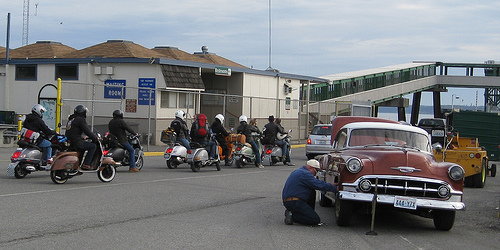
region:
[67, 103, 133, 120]
the helmets are black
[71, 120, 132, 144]
the clothing is black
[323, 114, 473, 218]
the car is brown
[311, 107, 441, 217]
the car is under repair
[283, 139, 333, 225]
the man is kneeling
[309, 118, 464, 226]
the car is a classic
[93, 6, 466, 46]
the sky is cloudy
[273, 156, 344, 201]
the man has a blue shirt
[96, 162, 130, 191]
the tyre has a white stripe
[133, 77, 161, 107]
there is blue writing on the wall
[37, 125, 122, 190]
A brown motor bike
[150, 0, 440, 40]
A mostly cloudy sky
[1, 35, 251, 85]
Brown, triangular roof tops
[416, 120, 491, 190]
A yellow car trailer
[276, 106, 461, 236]
A man fixing his car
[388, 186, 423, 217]
The car's license plate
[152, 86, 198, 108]
Windows on the building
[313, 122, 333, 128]
A car's brake light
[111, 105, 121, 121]
A black helmet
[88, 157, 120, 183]
A motor bike wheel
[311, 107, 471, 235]
A red classic car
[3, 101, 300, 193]
A group riding their motor bikes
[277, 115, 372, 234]
A man changing his tire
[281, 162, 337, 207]
A blue long sleeve shirt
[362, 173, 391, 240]
A metal car jack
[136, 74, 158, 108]
A blue sign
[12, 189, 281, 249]
A crack in the street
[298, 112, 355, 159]
The back of a silver car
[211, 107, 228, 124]
A white helmet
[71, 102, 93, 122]
A black helmet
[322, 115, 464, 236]
An older car is on the side on the road.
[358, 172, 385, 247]
There is a jack on the front bumper.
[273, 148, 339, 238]
The man is kneeling on the ground.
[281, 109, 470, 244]
The man is changing a tire.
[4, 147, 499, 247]
The asphalt is dry.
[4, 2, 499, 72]
The sky is blue with white ripples of clouds.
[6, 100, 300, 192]
Many people are riding motorcycles down the street.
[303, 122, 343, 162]
There is a white car in front of all the motorcycles.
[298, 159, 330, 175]
The man is wearing a white cap.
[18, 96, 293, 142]
Most of the motorcyclists are wearing helmets.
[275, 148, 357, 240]
the man is fixing his tire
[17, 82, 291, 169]
the people are riding the motorcycles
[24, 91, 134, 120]
people are wearing helmets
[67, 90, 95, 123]
the helmet is black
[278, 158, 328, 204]
the shirt is blue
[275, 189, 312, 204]
the belt is brown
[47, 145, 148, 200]
the motorcycle is brown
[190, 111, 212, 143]
the bag is red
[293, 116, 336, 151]
the car is silver